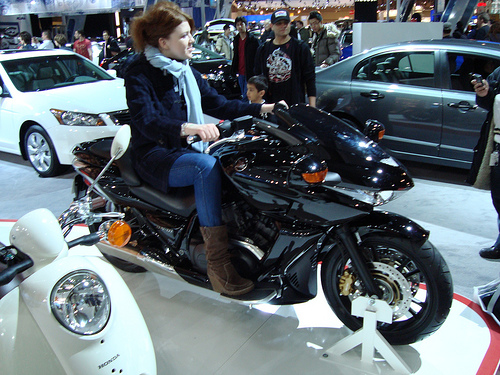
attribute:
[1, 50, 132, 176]
car — white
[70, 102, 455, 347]
bike — black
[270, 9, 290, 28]
hat — black, white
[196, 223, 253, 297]
boot — brown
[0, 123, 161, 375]
scooter — white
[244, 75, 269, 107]
boy — small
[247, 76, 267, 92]
hair — dark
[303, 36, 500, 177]
car — grayish-black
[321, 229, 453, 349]
wheel — black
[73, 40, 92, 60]
shirt — red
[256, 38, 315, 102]
shirt — black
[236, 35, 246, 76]
shirt — bergundy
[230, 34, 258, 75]
jacket — black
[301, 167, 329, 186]
blinker — orange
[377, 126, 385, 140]
blinker — orange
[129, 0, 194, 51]
hair — brown